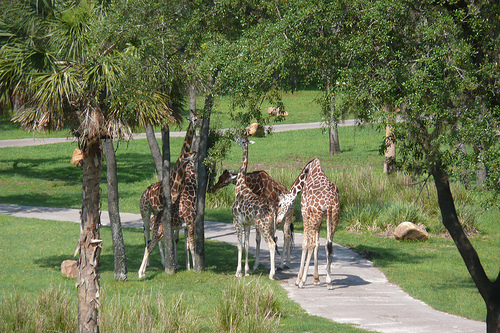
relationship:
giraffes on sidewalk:
[135, 115, 346, 288] [1, 185, 497, 331]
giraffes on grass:
[135, 115, 346, 288] [0, 212, 366, 332]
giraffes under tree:
[135, 115, 346, 288] [0, 1, 177, 332]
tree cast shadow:
[0, 0, 153, 333] [0, 149, 153, 210]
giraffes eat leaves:
[135, 115, 346, 288] [198, 131, 242, 209]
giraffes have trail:
[135, 115, 346, 288] [0, 105, 492, 332]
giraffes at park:
[135, 115, 346, 288] [0, 0, 500, 333]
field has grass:
[4, 120, 491, 332] [0, 212, 366, 332]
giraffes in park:
[135, 115, 346, 288] [1, 5, 499, 329]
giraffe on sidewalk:
[275, 157, 341, 290] [1, 185, 497, 331]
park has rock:
[1, 5, 499, 329] [392, 220, 432, 243]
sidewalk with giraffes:
[1, 185, 497, 331] [135, 115, 346, 288]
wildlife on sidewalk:
[138, 110, 335, 288] [1, 185, 497, 331]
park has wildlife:
[1, 5, 499, 329] [138, 110, 335, 288]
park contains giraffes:
[1, 5, 499, 329] [135, 115, 346, 288]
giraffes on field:
[135, 115, 346, 288] [4, 120, 491, 332]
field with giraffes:
[4, 120, 491, 332] [135, 115, 346, 288]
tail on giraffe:
[327, 204, 335, 260] [280, 157, 343, 289]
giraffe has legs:
[280, 157, 343, 289] [296, 212, 342, 286]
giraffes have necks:
[135, 115, 346, 288] [174, 131, 263, 181]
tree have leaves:
[0, 1, 177, 332] [198, 131, 242, 209]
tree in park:
[0, 1, 177, 332] [1, 5, 499, 329]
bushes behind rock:
[215, 158, 483, 223] [392, 220, 432, 243]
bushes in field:
[215, 158, 483, 223] [4, 120, 491, 332]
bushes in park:
[215, 158, 483, 223] [1, 5, 499, 329]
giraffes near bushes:
[135, 115, 346, 288] [215, 158, 483, 223]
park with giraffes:
[1, 5, 499, 329] [135, 115, 346, 288]